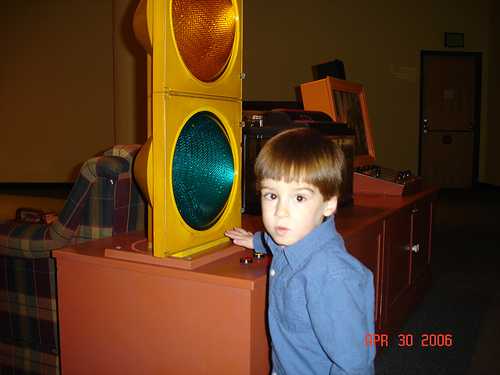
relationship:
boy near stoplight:
[222, 126, 377, 373] [132, 0, 244, 262]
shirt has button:
[253, 216, 377, 374] [267, 267, 278, 280]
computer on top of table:
[299, 76, 423, 200] [50, 182, 441, 375]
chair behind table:
[3, 141, 147, 375] [50, 182, 441, 375]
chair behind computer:
[3, 141, 147, 375] [299, 76, 423, 200]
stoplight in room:
[132, 0, 244, 262] [2, 2, 499, 375]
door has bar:
[419, 51, 482, 188] [423, 118, 478, 141]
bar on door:
[423, 118, 478, 141] [419, 51, 482, 188]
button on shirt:
[267, 267, 278, 280] [253, 216, 377, 374]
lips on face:
[272, 223, 294, 235] [260, 167, 325, 245]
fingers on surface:
[223, 226, 252, 246] [173, 225, 241, 262]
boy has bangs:
[222, 126, 377, 373] [255, 146, 334, 184]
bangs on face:
[255, 146, 334, 184] [260, 167, 325, 245]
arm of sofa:
[3, 218, 64, 257] [3, 141, 147, 375]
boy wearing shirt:
[222, 126, 377, 373] [253, 216, 377, 374]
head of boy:
[254, 128, 344, 244] [222, 126, 377, 373]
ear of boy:
[321, 194, 337, 216] [222, 126, 377, 373]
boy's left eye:
[222, 126, 377, 373] [266, 191, 278, 202]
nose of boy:
[276, 197, 290, 221] [222, 126, 377, 373]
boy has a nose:
[222, 126, 377, 373] [276, 197, 290, 221]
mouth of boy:
[272, 223, 294, 235] [222, 126, 377, 373]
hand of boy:
[223, 226, 252, 246] [222, 126, 377, 373]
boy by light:
[222, 126, 377, 373] [169, 105, 235, 233]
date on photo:
[364, 333, 453, 347] [2, 2, 499, 375]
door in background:
[419, 51, 482, 188] [3, 1, 500, 188]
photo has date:
[2, 2, 499, 375] [364, 333, 453, 347]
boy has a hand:
[222, 126, 377, 373] [223, 226, 252, 246]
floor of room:
[2, 189, 500, 374] [2, 2, 499, 375]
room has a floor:
[2, 2, 499, 375] [2, 189, 500, 374]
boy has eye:
[222, 126, 377, 373] [293, 192, 309, 203]